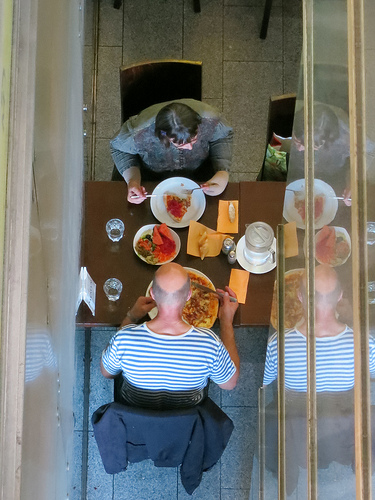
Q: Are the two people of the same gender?
A: No, they are both male and female.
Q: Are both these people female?
A: No, they are both male and female.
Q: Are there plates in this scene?
A: Yes, there is a plate.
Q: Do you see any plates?
A: Yes, there is a plate.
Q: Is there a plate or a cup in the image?
A: Yes, there is a plate.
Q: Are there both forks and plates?
A: Yes, there are both a plate and a fork.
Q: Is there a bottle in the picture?
A: No, there are no bottles.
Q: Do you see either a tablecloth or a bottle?
A: No, there are no bottles or tablecloths.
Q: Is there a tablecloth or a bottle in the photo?
A: No, there are no bottles or tablecloths.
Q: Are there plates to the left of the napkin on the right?
A: Yes, there is a plate to the left of the napkin.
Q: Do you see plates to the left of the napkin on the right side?
A: Yes, there is a plate to the left of the napkin.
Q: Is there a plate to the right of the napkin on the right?
A: No, the plate is to the left of the napkin.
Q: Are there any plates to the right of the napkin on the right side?
A: No, the plate is to the left of the napkin.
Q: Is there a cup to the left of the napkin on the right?
A: No, there is a plate to the left of the napkin.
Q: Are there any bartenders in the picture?
A: No, there are no bartenders.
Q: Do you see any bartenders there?
A: No, there are no bartenders.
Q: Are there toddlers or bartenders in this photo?
A: No, there are no bartenders or toddlers.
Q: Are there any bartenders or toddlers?
A: No, there are no bartenders or toddlers.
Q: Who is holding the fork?
A: The man is holding the fork.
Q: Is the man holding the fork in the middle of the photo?
A: Yes, the man is holding the fork.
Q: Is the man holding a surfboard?
A: No, the man is holding the fork.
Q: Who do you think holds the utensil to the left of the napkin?
A: The man holds the knife.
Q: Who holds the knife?
A: The man holds the knife.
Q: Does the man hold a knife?
A: Yes, the man holds a knife.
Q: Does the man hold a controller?
A: No, the man holds a knife.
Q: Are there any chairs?
A: Yes, there is a chair.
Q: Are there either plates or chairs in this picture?
A: Yes, there is a chair.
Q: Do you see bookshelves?
A: No, there are no bookshelves.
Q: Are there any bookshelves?
A: No, there are no bookshelves.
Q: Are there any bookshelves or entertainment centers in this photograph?
A: No, there are no bookshelves or entertainment centers.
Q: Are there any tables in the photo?
A: Yes, there is a table.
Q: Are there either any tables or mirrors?
A: Yes, there is a table.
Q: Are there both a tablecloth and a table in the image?
A: No, there is a table but no tablecloths.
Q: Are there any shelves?
A: No, there are no shelves.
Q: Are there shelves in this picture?
A: No, there are no shelves.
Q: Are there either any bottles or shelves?
A: No, there are no shelves or bottles.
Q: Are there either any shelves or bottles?
A: No, there are no shelves or bottles.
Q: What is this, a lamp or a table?
A: This is a table.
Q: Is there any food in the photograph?
A: Yes, there is food.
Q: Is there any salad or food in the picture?
A: Yes, there is food.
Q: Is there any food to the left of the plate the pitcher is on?
A: Yes, there is food to the left of the plate.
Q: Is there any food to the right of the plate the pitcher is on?
A: No, the food is to the left of the plate.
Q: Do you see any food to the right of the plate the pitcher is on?
A: No, the food is to the left of the plate.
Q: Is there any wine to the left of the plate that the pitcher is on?
A: No, there is food to the left of the plate.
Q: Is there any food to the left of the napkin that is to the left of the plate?
A: Yes, there is food to the left of the napkin.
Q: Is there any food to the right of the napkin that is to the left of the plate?
A: No, the food is to the left of the napkin.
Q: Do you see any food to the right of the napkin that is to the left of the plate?
A: No, the food is to the left of the napkin.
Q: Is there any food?
A: Yes, there is food.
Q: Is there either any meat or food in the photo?
A: Yes, there is food.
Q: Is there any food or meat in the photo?
A: Yes, there is food.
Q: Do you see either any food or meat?
A: Yes, there is food.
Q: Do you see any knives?
A: Yes, there is a knife.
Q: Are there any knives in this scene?
A: Yes, there is a knife.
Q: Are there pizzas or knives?
A: Yes, there is a knife.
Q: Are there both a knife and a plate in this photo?
A: Yes, there are both a knife and a plate.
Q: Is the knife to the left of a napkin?
A: Yes, the knife is to the left of a napkin.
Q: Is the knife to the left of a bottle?
A: No, the knife is to the left of a napkin.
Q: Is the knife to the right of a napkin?
A: No, the knife is to the left of a napkin.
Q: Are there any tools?
A: No, there are no tools.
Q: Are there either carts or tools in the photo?
A: No, there are no tools or carts.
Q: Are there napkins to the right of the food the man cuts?
A: Yes, there is a napkin to the right of the food.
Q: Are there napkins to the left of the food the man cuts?
A: No, the napkin is to the right of the food.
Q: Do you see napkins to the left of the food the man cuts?
A: No, the napkin is to the right of the food.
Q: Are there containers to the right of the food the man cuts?
A: No, there is a napkin to the right of the food.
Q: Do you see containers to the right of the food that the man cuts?
A: No, there is a napkin to the right of the food.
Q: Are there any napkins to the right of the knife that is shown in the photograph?
A: Yes, there is a napkin to the right of the knife.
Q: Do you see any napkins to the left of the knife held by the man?
A: No, the napkin is to the right of the knife.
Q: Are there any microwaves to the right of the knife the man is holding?
A: No, there is a napkin to the right of the knife.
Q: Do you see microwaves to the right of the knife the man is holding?
A: No, there is a napkin to the right of the knife.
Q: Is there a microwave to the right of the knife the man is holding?
A: No, there is a napkin to the right of the knife.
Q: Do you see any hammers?
A: No, there are no hammers.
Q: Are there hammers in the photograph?
A: No, there are no hammers.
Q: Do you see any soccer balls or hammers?
A: No, there are no hammers or soccer balls.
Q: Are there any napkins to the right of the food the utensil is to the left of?
A: Yes, there are napkins to the right of the food.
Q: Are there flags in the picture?
A: No, there are no flags.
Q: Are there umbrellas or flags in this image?
A: No, there are no flags or umbrellas.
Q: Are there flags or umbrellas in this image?
A: No, there are no flags or umbrellas.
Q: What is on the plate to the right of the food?
A: The pitcher is on the plate.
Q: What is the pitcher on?
A: The pitcher is on the plate.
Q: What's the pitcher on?
A: The pitcher is on the plate.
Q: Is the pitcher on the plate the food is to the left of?
A: Yes, the pitcher is on the plate.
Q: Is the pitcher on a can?
A: No, the pitcher is on the plate.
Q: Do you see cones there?
A: No, there are no cones.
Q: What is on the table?
A: The glass is on the table.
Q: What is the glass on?
A: The glass is on the table.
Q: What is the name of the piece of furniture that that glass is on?
A: The piece of furniture is a table.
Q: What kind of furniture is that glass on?
A: The glass is on the table.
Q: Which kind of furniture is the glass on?
A: The glass is on the table.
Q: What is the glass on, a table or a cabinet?
A: The glass is on a table.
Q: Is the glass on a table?
A: Yes, the glass is on a table.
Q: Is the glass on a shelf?
A: No, the glass is on a table.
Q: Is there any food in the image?
A: Yes, there is food.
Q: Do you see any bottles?
A: No, there are no bottles.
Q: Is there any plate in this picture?
A: Yes, there is a plate.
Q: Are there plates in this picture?
A: Yes, there is a plate.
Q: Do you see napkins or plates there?
A: Yes, there is a plate.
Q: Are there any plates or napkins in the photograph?
A: Yes, there is a plate.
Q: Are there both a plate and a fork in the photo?
A: Yes, there are both a plate and a fork.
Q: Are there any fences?
A: No, there are no fences.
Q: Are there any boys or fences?
A: No, there are no fences or boys.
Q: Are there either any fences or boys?
A: No, there are no fences or boys.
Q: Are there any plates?
A: Yes, there is a plate.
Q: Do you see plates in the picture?
A: Yes, there is a plate.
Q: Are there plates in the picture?
A: Yes, there is a plate.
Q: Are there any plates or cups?
A: Yes, there is a plate.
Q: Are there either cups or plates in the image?
A: Yes, there is a plate.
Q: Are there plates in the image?
A: Yes, there is a plate.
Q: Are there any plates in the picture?
A: Yes, there is a plate.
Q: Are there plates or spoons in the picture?
A: Yes, there is a plate.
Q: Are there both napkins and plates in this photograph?
A: Yes, there are both a plate and a napkin.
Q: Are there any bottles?
A: No, there are no bottles.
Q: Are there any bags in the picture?
A: No, there are no bags.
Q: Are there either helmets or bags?
A: No, there are no bags or helmets.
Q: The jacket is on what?
A: The jacket is on the chair.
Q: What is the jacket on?
A: The jacket is on the chair.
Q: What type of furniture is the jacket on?
A: The jacket is on the chair.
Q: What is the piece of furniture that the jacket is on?
A: The piece of furniture is a chair.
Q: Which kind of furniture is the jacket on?
A: The jacket is on the chair.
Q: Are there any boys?
A: No, there are no boys.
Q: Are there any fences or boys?
A: No, there are no boys or fences.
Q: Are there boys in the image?
A: No, there are no boys.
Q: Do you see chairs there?
A: Yes, there is a chair.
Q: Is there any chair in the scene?
A: Yes, there is a chair.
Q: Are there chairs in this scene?
A: Yes, there is a chair.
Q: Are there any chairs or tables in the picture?
A: Yes, there is a chair.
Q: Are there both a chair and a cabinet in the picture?
A: No, there is a chair but no cabinets.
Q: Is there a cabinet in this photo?
A: No, there are no cabinets.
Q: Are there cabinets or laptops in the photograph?
A: No, there are no cabinets or laptops.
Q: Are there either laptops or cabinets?
A: No, there are no cabinets or laptops.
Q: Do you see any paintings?
A: No, there are no paintings.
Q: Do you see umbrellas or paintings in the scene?
A: No, there are no paintings or umbrellas.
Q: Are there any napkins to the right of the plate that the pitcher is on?
A: Yes, there is a napkin to the right of the plate.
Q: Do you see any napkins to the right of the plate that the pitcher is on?
A: Yes, there is a napkin to the right of the plate.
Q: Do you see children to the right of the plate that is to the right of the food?
A: No, there is a napkin to the right of the plate.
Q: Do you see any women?
A: Yes, there is a woman.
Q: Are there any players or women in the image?
A: Yes, there is a woman.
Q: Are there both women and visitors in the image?
A: No, there is a woman but no visitors.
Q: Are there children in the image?
A: No, there are no children.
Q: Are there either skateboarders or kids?
A: No, there are no kids or skateboarders.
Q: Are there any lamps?
A: No, there are no lamps.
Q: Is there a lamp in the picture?
A: No, there are no lamps.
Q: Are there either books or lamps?
A: No, there are no lamps or books.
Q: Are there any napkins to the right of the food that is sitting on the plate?
A: Yes, there is a napkin to the right of the food.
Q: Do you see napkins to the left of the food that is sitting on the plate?
A: No, the napkin is to the right of the food.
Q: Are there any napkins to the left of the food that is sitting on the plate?
A: No, the napkin is to the right of the food.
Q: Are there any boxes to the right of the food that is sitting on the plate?
A: No, there is a napkin to the right of the food.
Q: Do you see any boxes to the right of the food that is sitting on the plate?
A: No, there is a napkin to the right of the food.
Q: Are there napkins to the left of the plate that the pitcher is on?
A: Yes, there is a napkin to the left of the plate.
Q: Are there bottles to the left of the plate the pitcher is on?
A: No, there is a napkin to the left of the plate.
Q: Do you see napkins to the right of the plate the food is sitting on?
A: Yes, there is a napkin to the right of the plate.